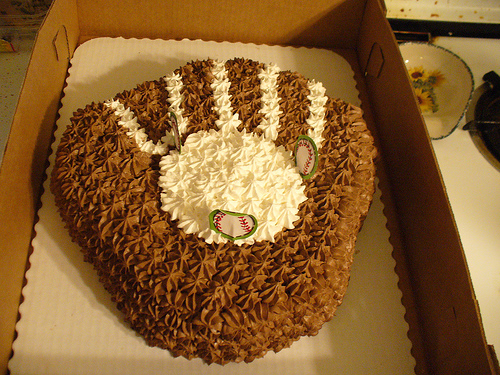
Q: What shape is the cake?
A: Ball glove.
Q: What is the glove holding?
A: Baseball.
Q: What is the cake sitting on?
A: Paper.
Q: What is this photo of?
A: A table.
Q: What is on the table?
A: A cake.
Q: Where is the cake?
A: In a box.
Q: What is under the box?
A: A sheet paper.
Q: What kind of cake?
A: A mitt.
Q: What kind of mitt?
A: A catcher's mitt.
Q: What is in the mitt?
A: A baseball.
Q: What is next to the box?
A: A bowl.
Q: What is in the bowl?
A: A design.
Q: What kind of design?
A: Flower.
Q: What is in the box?
A: Cake.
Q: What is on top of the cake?
A: Frosting.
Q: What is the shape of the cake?
A: Glove.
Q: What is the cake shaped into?
A: A baseball mitt.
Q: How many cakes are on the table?
A: 1.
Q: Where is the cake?
A: In the box.